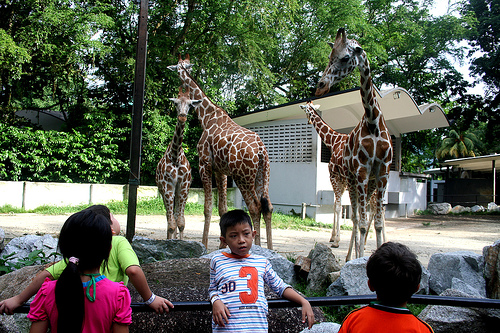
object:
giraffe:
[168, 55, 275, 254]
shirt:
[28, 273, 131, 332]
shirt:
[43, 234, 142, 287]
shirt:
[206, 250, 293, 333]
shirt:
[337, 301, 432, 332]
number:
[238, 265, 259, 304]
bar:
[1, 293, 500, 311]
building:
[232, 86, 451, 221]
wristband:
[211, 295, 221, 304]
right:
[221, 1, 499, 332]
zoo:
[1, 0, 500, 333]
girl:
[27, 212, 132, 332]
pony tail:
[54, 256, 85, 332]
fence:
[0, 179, 237, 214]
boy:
[340, 242, 436, 332]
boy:
[207, 209, 314, 332]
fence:
[3, 291, 499, 332]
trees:
[1, 1, 114, 121]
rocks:
[418, 274, 490, 332]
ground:
[0, 204, 499, 270]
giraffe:
[314, 25, 389, 265]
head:
[317, 25, 364, 97]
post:
[300, 202, 307, 221]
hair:
[55, 208, 115, 332]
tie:
[68, 256, 80, 265]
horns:
[341, 28, 347, 43]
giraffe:
[156, 94, 201, 242]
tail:
[258, 151, 270, 215]